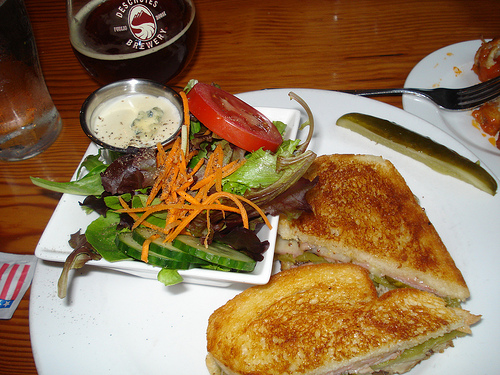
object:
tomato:
[188, 82, 284, 165]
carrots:
[112, 91, 273, 264]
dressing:
[90, 91, 166, 149]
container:
[85, 94, 170, 188]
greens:
[66, 182, 153, 280]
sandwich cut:
[249, 150, 474, 300]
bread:
[289, 314, 363, 344]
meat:
[365, 351, 416, 372]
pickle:
[335, 111, 496, 192]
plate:
[355, 115, 496, 299]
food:
[48, 83, 499, 374]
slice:
[195, 76, 303, 156]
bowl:
[78, 78, 185, 155]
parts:
[154, 156, 232, 218]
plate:
[28, 87, 498, 375]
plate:
[390, 37, 499, 175]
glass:
[0, 0, 65, 162]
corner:
[3, 2, 113, 177]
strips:
[133, 147, 271, 237]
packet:
[0, 251, 38, 322]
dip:
[90, 93, 179, 151]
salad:
[44, 82, 307, 282]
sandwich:
[194, 143, 469, 373]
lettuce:
[382, 335, 465, 370]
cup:
[74, 79, 185, 154]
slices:
[124, 226, 258, 279]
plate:
[33, 105, 303, 289]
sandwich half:
[203, 260, 486, 375]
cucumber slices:
[115, 223, 256, 273]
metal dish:
[85, 76, 188, 166]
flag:
[0, 257, 33, 321]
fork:
[343, 77, 496, 112]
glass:
[63, 0, 205, 91]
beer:
[69, 0, 199, 89]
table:
[0, 2, 500, 371]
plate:
[399, 39, 499, 174]